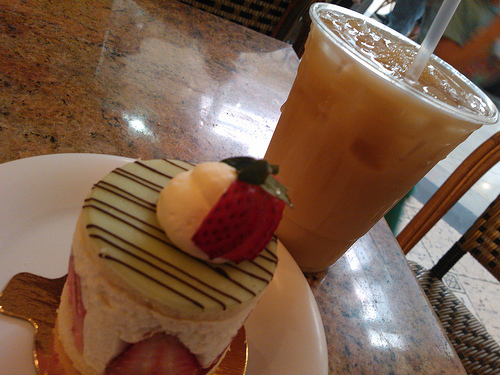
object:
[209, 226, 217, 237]
seed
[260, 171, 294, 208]
leaf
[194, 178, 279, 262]
strawberry slice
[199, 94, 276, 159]
light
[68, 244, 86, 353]
sauce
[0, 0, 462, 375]
counter top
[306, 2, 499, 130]
edge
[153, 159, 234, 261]
cream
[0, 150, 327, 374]
plate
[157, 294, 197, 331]
part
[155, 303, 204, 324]
edge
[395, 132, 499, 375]
chair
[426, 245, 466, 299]
part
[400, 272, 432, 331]
edge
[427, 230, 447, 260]
part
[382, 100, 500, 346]
floor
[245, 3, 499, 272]
clear cup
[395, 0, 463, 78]
clear straw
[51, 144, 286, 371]
pastry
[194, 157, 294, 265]
strawberries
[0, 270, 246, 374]
gold platter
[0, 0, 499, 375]
granite counter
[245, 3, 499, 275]
ice cubes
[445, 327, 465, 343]
square design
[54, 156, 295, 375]
cookie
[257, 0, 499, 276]
beverage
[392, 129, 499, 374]
wicker chair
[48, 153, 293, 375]
appetizer dish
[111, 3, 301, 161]
reflection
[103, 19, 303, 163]
sunlight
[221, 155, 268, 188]
leaf